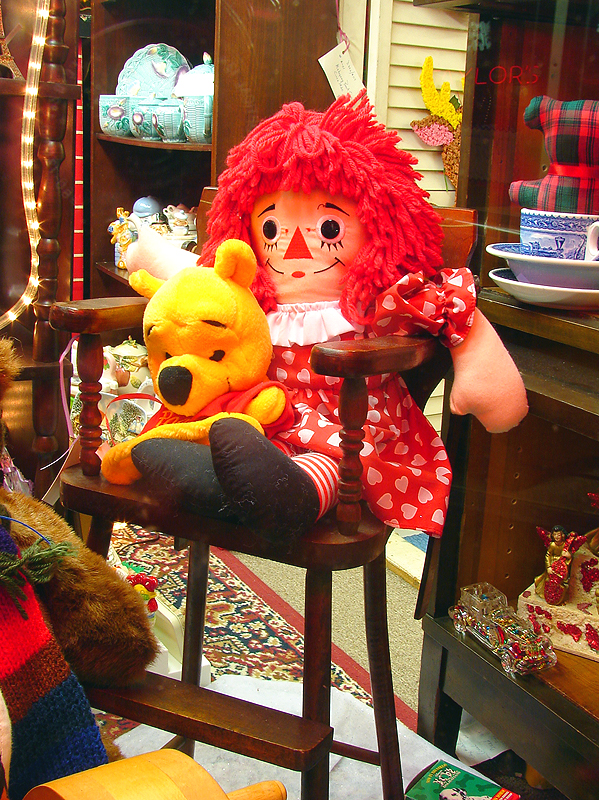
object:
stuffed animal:
[100, 238, 294, 485]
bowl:
[484, 239, 598, 292]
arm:
[50, 297, 150, 334]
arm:
[310, 336, 439, 379]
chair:
[47, 186, 479, 796]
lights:
[0, 0, 50, 331]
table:
[415, 284, 597, 798]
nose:
[158, 366, 193, 407]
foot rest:
[86, 668, 334, 771]